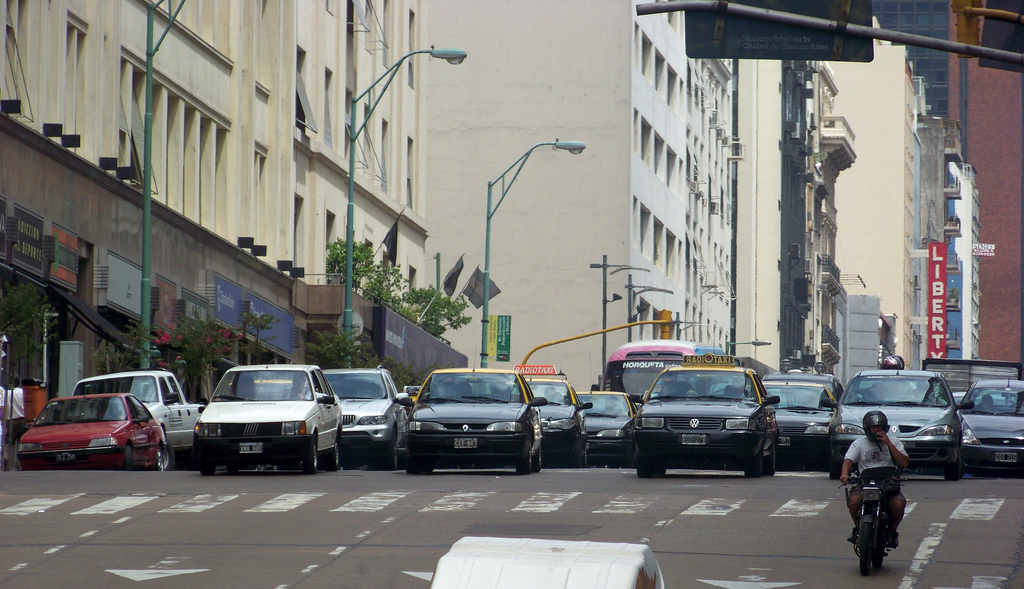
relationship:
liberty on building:
[920, 233, 948, 366] [811, 20, 945, 372]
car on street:
[629, 354, 779, 477] [2, 378, 1023, 584]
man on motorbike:
[837, 411, 909, 576] [839, 413, 941, 509]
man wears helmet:
[837, 411, 909, 576] [860, 408, 892, 444]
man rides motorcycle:
[837, 411, 909, 576] [836, 472, 907, 574]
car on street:
[836, 367, 957, 467] [2, 378, 1023, 584]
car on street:
[628, 361, 784, 466] [2, 378, 1023, 584]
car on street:
[396, 367, 548, 470] [2, 378, 1023, 584]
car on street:
[194, 358, 347, 473] [2, 378, 1023, 584]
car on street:
[318, 361, 416, 454] [2, 378, 1023, 584]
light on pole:
[547, 129, 595, 159] [462, 154, 523, 355]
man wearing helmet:
[837, 409, 913, 511] [841, 395, 911, 441]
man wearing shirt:
[837, 411, 909, 576] [837, 431, 915, 481]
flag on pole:
[379, 216, 400, 267] [358, 203, 404, 276]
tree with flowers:
[153, 313, 239, 403] [157, 329, 177, 356]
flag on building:
[419, 254, 462, 312] [263, 57, 559, 416]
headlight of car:
[481, 410, 527, 445] [399, 352, 558, 476]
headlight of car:
[639, 406, 668, 436] [622, 357, 784, 475]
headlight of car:
[963, 427, 977, 444] [959, 379, 1020, 477]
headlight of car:
[802, 421, 831, 437] [760, 376, 838, 469]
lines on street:
[2, 490, 1017, 513] [9, 466, 1016, 581]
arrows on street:
[74, 519, 234, 586] [1, 447, 1019, 585]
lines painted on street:
[1, 471, 994, 536] [9, 466, 1016, 581]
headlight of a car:
[718, 413, 754, 439] [609, 282, 806, 514]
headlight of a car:
[79, 424, 123, 466] [5, 366, 185, 496]